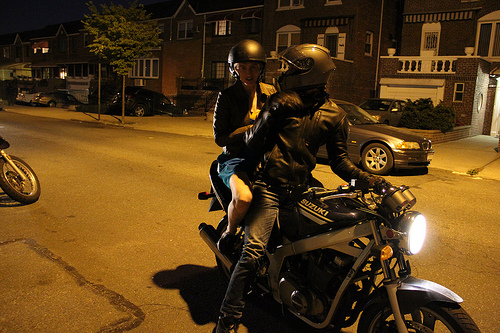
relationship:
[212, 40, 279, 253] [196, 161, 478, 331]
passenger on motorcycle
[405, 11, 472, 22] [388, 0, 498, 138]
stripe on building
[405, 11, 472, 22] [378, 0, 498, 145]
stripe on building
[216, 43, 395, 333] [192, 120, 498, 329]
driver on bike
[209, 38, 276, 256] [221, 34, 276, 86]
passenger wearing helmet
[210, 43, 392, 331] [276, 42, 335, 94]
driver wearing helmet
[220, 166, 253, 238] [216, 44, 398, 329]
leg of passenger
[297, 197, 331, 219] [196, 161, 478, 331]
name on motorcycle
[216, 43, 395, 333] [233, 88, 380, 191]
driver wearing jacket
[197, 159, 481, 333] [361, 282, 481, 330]
bike has tire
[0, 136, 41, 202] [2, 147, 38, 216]
bike has tire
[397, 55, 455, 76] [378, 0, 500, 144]
balcony on building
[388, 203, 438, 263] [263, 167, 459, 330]
headlight on motorcycle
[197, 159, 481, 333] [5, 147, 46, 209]
bike has wheel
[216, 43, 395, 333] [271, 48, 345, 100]
driver wearing helmet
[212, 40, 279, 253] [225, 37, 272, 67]
passenger wearing helmet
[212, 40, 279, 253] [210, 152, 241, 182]
passenger wearing short pants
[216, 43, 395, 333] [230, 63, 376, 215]
driver wearing jacket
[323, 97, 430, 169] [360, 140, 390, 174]
car has wheel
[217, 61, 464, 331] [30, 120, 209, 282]
vehicles traveling on street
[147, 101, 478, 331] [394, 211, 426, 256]
bike has headlight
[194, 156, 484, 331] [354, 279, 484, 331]
bike has tire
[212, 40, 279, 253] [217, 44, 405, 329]
passenger behind rider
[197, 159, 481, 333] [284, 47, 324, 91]
bike has head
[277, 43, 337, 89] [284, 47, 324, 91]
helmet on head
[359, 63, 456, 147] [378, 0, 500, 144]
garage in building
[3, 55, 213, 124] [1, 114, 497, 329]
vehicles on street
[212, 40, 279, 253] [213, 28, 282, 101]
passenger wearing helmet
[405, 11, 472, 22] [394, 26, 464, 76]
stripe on building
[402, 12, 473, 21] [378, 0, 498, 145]
stripe on building